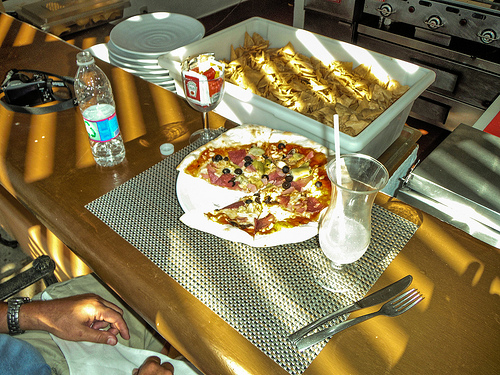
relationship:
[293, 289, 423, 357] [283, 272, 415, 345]
fork and knife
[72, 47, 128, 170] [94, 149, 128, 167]
bottle of water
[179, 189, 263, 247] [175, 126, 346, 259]
slice missing from pizza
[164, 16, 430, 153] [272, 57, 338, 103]
box of chips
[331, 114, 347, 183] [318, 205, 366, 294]
straw in glass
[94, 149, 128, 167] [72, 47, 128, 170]
water in bottle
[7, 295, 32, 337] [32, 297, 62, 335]
watch on write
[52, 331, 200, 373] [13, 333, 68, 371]
napkin in lap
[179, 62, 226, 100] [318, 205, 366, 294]
sauce in glass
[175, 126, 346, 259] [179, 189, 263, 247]
pizza with slice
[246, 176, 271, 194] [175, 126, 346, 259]
ham on pizza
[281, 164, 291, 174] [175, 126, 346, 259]
olive on pizza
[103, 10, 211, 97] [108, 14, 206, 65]
stack of plates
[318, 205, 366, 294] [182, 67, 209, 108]
glass of packets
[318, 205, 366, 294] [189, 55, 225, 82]
glass of condiments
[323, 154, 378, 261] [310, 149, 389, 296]
tiki style cup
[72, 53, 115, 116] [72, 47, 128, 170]
plastic water bottle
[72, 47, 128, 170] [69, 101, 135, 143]
bottle with lable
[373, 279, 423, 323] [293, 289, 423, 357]
silver eating utensils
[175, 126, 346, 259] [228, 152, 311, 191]
pizza with toppings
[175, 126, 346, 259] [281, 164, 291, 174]
pizza with olive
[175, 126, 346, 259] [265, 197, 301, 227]
pizza with cheese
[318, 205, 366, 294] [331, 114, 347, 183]
glass with straw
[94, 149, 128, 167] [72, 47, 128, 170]
water nearly empty bottle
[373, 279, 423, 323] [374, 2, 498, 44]
silver and dials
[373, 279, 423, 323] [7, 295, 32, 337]
silver wrist watch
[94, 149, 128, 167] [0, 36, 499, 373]
water on table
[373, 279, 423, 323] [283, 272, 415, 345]
silver knife utensil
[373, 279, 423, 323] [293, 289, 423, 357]
silver untensil fork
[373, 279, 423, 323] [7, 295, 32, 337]
silver mans watch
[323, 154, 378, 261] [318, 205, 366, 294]
fluted clear glass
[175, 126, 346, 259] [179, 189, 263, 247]
pizza pie slice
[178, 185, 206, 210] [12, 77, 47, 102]
white and black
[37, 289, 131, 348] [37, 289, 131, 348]
hand left hand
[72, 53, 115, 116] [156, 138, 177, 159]
plastic bottle lid